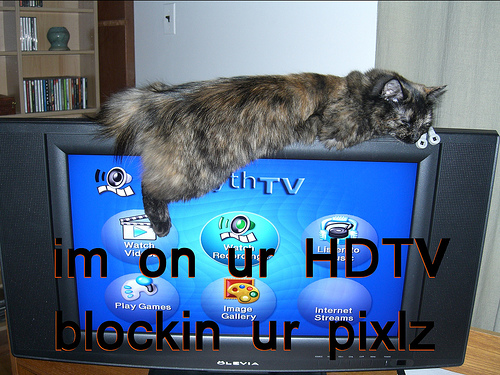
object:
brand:
[216, 359, 259, 366]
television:
[2, 117, 498, 374]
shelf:
[23, 53, 98, 114]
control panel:
[317, 358, 414, 367]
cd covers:
[82, 77, 86, 109]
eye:
[400, 118, 412, 127]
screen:
[67, 153, 419, 339]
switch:
[161, 2, 176, 33]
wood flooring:
[442, 327, 499, 374]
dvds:
[43, 79, 48, 112]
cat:
[82, 68, 447, 236]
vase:
[47, 26, 72, 50]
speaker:
[412, 141, 496, 357]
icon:
[224, 278, 260, 303]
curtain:
[373, 0, 498, 131]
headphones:
[427, 126, 440, 144]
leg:
[140, 126, 213, 200]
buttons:
[314, 355, 323, 357]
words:
[140, 247, 165, 278]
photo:
[0, 0, 497, 374]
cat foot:
[143, 196, 173, 238]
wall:
[133, 1, 378, 89]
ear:
[378, 74, 405, 99]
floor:
[440, 328, 499, 374]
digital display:
[67, 155, 422, 336]